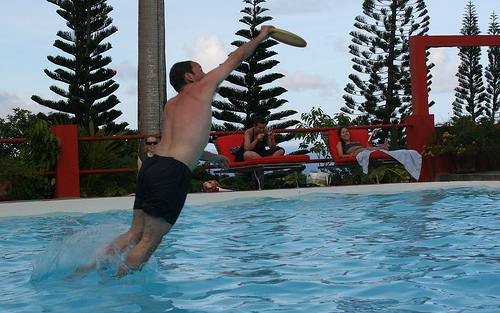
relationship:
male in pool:
[61, 25, 276, 287] [25, 214, 474, 313]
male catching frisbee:
[61, 25, 276, 287] [265, 22, 330, 55]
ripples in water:
[250, 216, 434, 255] [43, 216, 493, 276]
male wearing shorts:
[61, 25, 276, 287] [145, 161, 194, 199]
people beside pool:
[232, 120, 395, 175] [25, 214, 474, 313]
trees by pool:
[49, 18, 418, 130] [25, 214, 474, 313]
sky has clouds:
[181, 9, 467, 83] [193, 36, 246, 65]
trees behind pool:
[49, 18, 418, 130] [25, 214, 474, 313]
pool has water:
[25, 214, 474, 313] [43, 216, 493, 276]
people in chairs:
[232, 120, 395, 175] [213, 134, 311, 193]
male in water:
[61, 25, 276, 287] [59, 228, 126, 276]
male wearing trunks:
[154, 85, 235, 268] [129, 155, 188, 215]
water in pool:
[43, 216, 493, 276] [25, 214, 474, 313]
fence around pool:
[28, 113, 179, 184] [25, 214, 474, 313]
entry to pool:
[434, 110, 494, 167] [25, 214, 474, 313]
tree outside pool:
[228, 1, 285, 131] [25, 214, 474, 313]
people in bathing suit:
[337, 126, 409, 157] [343, 140, 362, 154]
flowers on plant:
[437, 131, 470, 153] [431, 130, 481, 179]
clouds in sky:
[193, 36, 246, 65] [181, 9, 467, 83]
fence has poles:
[28, 113, 179, 184] [38, 118, 73, 211]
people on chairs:
[232, 120, 395, 175] [220, 143, 401, 176]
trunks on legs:
[129, 155, 188, 215] [107, 220, 158, 278]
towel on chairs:
[386, 145, 427, 176] [220, 143, 401, 176]